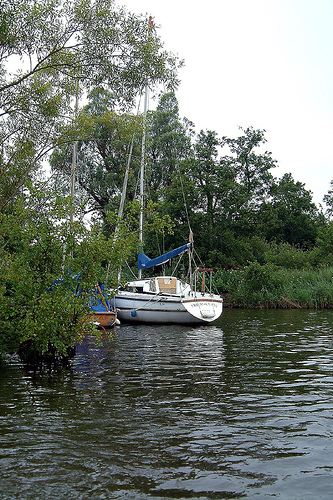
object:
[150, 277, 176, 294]
trim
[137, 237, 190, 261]
pole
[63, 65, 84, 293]
poles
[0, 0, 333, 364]
greenery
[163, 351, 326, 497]
water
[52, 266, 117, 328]
boat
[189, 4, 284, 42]
light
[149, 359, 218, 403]
ripples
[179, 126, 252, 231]
trees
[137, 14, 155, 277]
pole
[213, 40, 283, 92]
sky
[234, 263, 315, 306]
land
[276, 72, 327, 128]
no clouds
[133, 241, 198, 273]
part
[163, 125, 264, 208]
branches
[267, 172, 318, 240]
tree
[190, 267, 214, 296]
poles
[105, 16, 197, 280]
sails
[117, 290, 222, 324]
trim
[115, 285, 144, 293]
window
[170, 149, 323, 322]
area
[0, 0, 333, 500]
day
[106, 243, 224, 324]
boat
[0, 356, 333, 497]
river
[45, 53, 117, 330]
sailboat